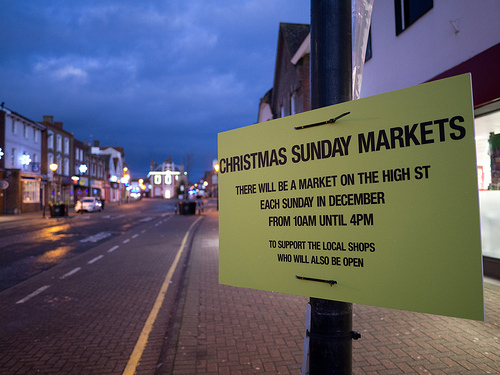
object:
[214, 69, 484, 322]
sign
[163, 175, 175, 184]
rooms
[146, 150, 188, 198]
building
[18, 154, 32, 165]
lights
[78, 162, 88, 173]
lights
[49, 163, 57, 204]
light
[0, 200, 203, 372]
street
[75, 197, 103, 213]
car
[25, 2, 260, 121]
clouds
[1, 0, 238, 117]
sky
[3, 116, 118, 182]
windows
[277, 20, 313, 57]
roof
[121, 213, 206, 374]
line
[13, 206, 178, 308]
lines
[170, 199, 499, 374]
sidewalk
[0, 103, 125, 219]
buildings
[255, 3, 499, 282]
buildings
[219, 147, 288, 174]
christmas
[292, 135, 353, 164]
sunday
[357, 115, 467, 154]
markets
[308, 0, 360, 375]
light pole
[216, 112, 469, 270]
letters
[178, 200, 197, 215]
trash can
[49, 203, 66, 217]
trash can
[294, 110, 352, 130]
zip tie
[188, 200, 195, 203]
garbage dumpster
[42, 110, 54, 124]
chimney